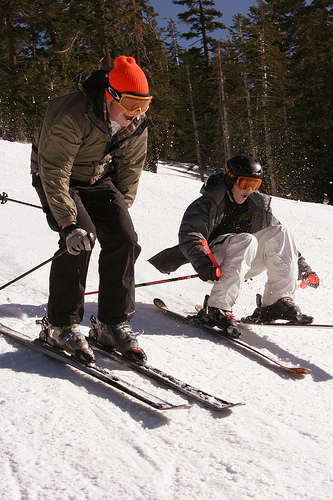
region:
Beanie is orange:
[103, 55, 150, 101]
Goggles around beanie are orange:
[106, 54, 150, 98]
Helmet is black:
[224, 150, 264, 185]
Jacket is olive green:
[32, 91, 147, 226]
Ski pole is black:
[0, 223, 96, 300]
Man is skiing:
[29, 55, 155, 366]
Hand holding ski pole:
[60, 222, 94, 253]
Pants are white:
[204, 225, 299, 313]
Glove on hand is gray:
[62, 225, 95, 255]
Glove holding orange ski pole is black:
[198, 261, 221, 287]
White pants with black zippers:
[206, 223, 295, 310]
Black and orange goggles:
[104, 72, 153, 116]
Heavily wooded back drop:
[2, 0, 331, 206]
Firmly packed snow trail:
[1, 139, 331, 497]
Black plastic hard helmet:
[225, 152, 264, 179]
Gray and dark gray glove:
[58, 221, 91, 256]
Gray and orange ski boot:
[45, 321, 90, 356]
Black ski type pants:
[30, 171, 142, 326]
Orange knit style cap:
[108, 53, 149, 95]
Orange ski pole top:
[214, 267, 220, 278]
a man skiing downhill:
[0, 50, 250, 422]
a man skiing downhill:
[155, 154, 331, 376]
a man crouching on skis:
[150, 147, 331, 384]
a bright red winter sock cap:
[106, 53, 148, 105]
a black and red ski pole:
[56, 260, 221, 299]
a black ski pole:
[0, 188, 50, 215]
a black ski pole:
[0, 226, 95, 296]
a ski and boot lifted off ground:
[241, 295, 331, 331]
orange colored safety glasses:
[231, 173, 261, 193]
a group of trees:
[2, 1, 325, 201]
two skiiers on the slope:
[22, 52, 321, 336]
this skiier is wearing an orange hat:
[32, 51, 159, 336]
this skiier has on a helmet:
[208, 149, 291, 227]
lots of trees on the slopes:
[6, 3, 318, 80]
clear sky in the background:
[28, 6, 304, 74]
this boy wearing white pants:
[183, 159, 320, 374]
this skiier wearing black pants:
[29, 166, 175, 384]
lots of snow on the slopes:
[7, 159, 330, 445]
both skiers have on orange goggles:
[93, 65, 287, 206]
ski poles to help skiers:
[2, 191, 201, 312]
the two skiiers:
[70, 29, 276, 193]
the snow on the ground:
[22, 433, 116, 493]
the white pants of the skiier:
[213, 223, 321, 319]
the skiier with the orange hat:
[33, 51, 170, 498]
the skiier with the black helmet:
[208, 141, 312, 325]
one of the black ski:
[121, 380, 179, 429]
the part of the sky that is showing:
[225, 5, 242, 14]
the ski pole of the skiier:
[0, 187, 42, 225]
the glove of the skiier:
[295, 258, 318, 287]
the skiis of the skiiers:
[2, 307, 293, 404]